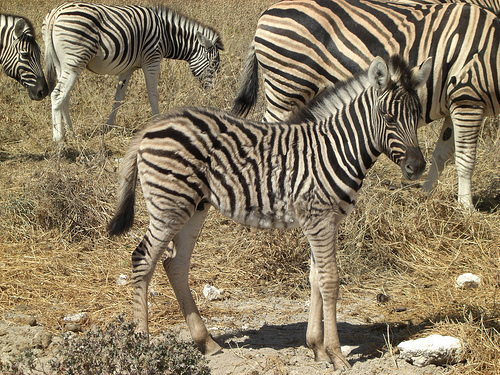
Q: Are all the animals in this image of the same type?
A: Yes, all the animals are zebras.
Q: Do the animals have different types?
A: No, all the animals are zebras.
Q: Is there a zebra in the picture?
A: Yes, there is a zebra.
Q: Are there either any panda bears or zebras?
A: Yes, there is a zebra.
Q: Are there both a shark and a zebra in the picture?
A: No, there is a zebra but no sharks.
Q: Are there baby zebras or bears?
A: Yes, there is a baby zebra.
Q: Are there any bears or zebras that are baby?
A: Yes, the zebra is a baby.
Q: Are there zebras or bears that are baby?
A: Yes, the zebra is a baby.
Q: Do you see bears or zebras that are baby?
A: Yes, the zebra is a baby.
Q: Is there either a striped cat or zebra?
A: Yes, there is a striped zebra.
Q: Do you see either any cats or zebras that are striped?
A: Yes, the zebra is striped.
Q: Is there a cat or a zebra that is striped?
A: Yes, the zebra is striped.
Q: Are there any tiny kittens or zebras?
A: Yes, there is a tiny zebra.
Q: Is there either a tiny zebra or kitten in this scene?
A: Yes, there is a tiny zebra.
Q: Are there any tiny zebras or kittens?
A: Yes, there is a tiny zebra.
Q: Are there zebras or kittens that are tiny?
A: Yes, the zebra is tiny.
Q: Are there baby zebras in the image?
A: Yes, there is a baby zebra.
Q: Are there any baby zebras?
A: Yes, there is a baby zebra.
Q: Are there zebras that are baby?
A: Yes, there is a zebra that is a baby.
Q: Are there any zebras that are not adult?
A: Yes, there is an baby zebra.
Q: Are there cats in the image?
A: No, there are no cats.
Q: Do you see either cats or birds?
A: No, there are no cats or birds.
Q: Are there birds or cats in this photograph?
A: No, there are no cats or birds.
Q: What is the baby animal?
A: The animal is a zebra.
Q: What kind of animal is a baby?
A: The animal is a zebra.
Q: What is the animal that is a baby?
A: The animal is a zebra.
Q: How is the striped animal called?
A: The animal is a zebra.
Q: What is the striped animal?
A: The animal is a zebra.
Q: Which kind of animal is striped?
A: The animal is a zebra.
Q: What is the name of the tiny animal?
A: The animal is a zebra.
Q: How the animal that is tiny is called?
A: The animal is a zebra.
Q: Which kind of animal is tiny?
A: The animal is a zebra.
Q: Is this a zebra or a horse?
A: This is a zebra.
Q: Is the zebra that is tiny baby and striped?
A: Yes, the zebra is a baby and striped.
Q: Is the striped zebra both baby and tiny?
A: Yes, the zebra is a baby and tiny.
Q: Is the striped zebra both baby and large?
A: No, the zebra is a baby but tiny.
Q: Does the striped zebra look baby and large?
A: No, the zebra is a baby but tiny.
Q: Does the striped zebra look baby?
A: Yes, the zebra is a baby.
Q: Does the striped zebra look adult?
A: No, the zebra is a baby.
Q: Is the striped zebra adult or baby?
A: The zebra is a baby.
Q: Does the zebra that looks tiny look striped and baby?
A: Yes, the zebra is striped and baby.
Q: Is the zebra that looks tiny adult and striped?
A: No, the zebra is striped but baby.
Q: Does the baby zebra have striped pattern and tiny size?
A: Yes, the zebra is striped and tiny.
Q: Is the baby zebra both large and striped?
A: No, the zebra is striped but tiny.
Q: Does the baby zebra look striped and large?
A: No, the zebra is striped but tiny.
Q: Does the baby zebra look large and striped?
A: No, the zebra is striped but tiny.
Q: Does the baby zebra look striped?
A: Yes, the zebra is striped.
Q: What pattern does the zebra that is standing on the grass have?
A: The zebra has striped pattern.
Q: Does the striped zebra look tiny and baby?
A: Yes, the zebra is tiny and baby.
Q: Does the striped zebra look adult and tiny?
A: No, the zebra is tiny but baby.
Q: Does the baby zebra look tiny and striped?
A: Yes, the zebra is tiny and striped.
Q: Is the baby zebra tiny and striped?
A: Yes, the zebra is tiny and striped.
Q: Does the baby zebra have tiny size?
A: Yes, the zebra is tiny.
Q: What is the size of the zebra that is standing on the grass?
A: The zebra is tiny.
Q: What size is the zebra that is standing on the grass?
A: The zebra is tiny.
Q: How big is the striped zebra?
A: The zebra is tiny.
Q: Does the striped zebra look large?
A: No, the zebra is tiny.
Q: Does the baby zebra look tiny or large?
A: The zebra is tiny.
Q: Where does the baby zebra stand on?
A: The zebra stands on the grass.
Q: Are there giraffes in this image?
A: No, there are no giraffes.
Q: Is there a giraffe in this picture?
A: No, there are no giraffes.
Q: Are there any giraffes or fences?
A: No, there are no giraffes or fences.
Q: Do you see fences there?
A: No, there are no fences.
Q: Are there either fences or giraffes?
A: No, there are no fences or giraffes.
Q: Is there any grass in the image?
A: Yes, there is grass.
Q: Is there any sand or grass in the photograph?
A: Yes, there is grass.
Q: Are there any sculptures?
A: No, there are no sculptures.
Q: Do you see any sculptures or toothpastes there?
A: No, there are no sculptures or toothpastes.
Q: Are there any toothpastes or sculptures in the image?
A: No, there are no sculptures or toothpastes.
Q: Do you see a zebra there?
A: Yes, there is a zebra.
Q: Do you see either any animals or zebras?
A: Yes, there is a zebra.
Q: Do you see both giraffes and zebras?
A: No, there is a zebra but no giraffes.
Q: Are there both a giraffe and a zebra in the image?
A: No, there is a zebra but no giraffes.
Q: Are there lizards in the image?
A: No, there are no lizards.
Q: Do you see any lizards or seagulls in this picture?
A: No, there are no lizards or seagulls.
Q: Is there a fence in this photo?
A: No, there are no fences.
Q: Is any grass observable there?
A: Yes, there is grass.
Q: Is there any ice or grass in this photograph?
A: Yes, there is grass.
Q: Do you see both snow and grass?
A: No, there is grass but no snow.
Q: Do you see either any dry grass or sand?
A: Yes, there is dry grass.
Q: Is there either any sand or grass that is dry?
A: Yes, the grass is dry.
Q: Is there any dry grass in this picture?
A: Yes, there is dry grass.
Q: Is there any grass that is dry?
A: Yes, there is grass that is dry.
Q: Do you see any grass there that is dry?
A: Yes, there is grass that is dry.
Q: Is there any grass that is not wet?
A: Yes, there is dry grass.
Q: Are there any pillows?
A: No, there are no pillows.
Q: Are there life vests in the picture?
A: No, there are no life vests.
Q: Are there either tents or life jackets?
A: No, there are no life jackets or tents.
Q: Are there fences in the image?
A: No, there are no fences.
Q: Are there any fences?
A: No, there are no fences.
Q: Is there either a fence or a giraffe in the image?
A: No, there are no fences or giraffes.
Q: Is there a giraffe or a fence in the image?
A: No, there are no fences or giraffes.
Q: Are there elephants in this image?
A: No, there are no elephants.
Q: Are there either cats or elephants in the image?
A: No, there are no elephants or cats.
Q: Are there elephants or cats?
A: No, there are no elephants or cats.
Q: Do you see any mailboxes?
A: No, there are no mailboxes.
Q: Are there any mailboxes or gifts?
A: No, there are no mailboxes or gifts.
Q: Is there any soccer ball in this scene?
A: No, there are no soccer balls.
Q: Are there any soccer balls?
A: No, there are no soccer balls.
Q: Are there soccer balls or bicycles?
A: No, there are no soccer balls or bicycles.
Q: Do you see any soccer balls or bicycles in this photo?
A: No, there are no soccer balls or bicycles.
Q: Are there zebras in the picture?
A: Yes, there are zebras.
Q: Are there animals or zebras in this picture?
A: Yes, there are zebras.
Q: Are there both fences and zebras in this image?
A: No, there are zebras but no fences.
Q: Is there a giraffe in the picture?
A: No, there are no giraffes.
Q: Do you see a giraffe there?
A: No, there are no giraffes.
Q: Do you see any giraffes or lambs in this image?
A: No, there are no giraffes or lambs.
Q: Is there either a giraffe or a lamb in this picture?
A: No, there are no giraffes or lambs.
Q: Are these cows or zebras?
A: These are zebras.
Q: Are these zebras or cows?
A: These are zebras.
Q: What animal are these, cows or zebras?
A: These are zebras.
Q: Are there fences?
A: No, there are no fences.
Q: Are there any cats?
A: No, there are no cats.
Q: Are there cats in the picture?
A: No, there are no cats.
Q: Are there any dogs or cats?
A: No, there are no cats or dogs.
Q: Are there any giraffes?
A: No, there are no giraffes.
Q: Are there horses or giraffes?
A: No, there are no giraffes or horses.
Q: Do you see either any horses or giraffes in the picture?
A: No, there are no giraffes or horses.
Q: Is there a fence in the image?
A: No, there are no fences.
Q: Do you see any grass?
A: Yes, there is grass.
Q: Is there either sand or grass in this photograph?
A: Yes, there is grass.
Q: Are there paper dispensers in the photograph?
A: No, there are no paper dispensers.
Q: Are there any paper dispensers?
A: No, there are no paper dispensers.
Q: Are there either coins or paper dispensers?
A: No, there are no paper dispensers or coins.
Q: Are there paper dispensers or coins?
A: No, there are no paper dispensers or coins.